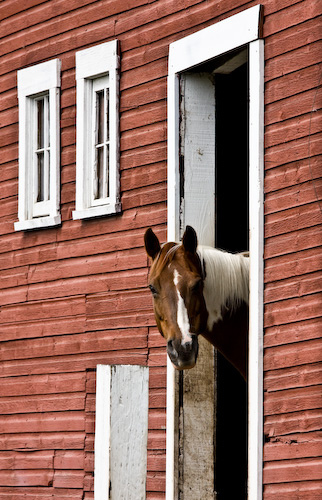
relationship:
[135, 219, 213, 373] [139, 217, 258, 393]
head of horse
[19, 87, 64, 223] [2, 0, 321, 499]
window of wall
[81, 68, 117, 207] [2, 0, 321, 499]
window of wall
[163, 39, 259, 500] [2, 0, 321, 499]
opening of wall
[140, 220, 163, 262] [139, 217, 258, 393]
ear on horse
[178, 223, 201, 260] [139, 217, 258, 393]
ear on horse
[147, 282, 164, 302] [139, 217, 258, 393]
eye of horse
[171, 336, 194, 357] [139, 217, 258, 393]
nose of horse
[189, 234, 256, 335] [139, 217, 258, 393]
fur of horse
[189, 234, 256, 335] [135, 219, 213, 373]
fur of head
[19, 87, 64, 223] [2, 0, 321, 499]
window on wall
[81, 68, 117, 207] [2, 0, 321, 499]
window on wall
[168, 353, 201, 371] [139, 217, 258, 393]
mouth of horse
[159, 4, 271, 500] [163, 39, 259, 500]
trim around opening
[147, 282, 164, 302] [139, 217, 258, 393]
eye on horse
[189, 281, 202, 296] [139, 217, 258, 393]
eye on horse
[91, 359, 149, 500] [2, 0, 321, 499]
pole outside wall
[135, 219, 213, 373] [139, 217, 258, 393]
head on horse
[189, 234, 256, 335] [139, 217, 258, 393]
fur on horse